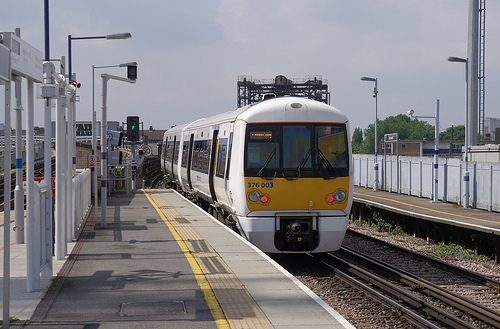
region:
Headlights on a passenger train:
[245, 188, 347, 203]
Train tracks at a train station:
[347, 225, 499, 326]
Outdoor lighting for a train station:
[66, 33, 135, 80]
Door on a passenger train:
[207, 128, 217, 202]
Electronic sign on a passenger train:
[245, 125, 277, 142]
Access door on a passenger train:
[208, 125, 220, 203]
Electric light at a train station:
[125, 115, 139, 142]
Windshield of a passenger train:
[246, 121, 350, 178]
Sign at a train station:
[2, 31, 44, 83]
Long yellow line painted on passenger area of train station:
[142, 187, 228, 327]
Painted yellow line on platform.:
[135, 183, 219, 326]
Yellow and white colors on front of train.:
[239, 98, 346, 259]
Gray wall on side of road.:
[357, 148, 494, 217]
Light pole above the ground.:
[61, 24, 133, 78]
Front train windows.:
[240, 116, 348, 179]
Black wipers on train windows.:
[240, 133, 350, 188]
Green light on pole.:
[122, 113, 144, 149]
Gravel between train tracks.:
[298, 260, 496, 302]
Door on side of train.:
[200, 125, 225, 203]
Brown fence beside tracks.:
[370, 195, 498, 255]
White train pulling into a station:
[153, 92, 359, 260]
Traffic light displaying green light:
[121, 109, 147, 190]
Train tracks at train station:
[293, 221, 499, 326]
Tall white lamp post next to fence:
[357, 70, 389, 191]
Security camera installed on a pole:
[402, 95, 445, 204]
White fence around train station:
[344, 143, 499, 217]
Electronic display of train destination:
[246, 126, 281, 143]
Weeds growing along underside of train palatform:
[348, 198, 498, 273]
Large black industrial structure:
[231, 68, 337, 111]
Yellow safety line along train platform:
[132, 182, 290, 327]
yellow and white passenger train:
[249, 112, 346, 204]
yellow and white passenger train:
[204, 117, 262, 206]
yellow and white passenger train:
[217, 104, 354, 255]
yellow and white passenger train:
[180, 127, 230, 193]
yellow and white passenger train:
[169, 137, 200, 179]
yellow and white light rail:
[248, 111, 348, 242]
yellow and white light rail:
[211, 119, 255, 200]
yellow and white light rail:
[184, 123, 234, 190]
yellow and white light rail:
[185, 133, 337, 215]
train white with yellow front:
[152, 97, 368, 265]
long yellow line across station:
[135, 185, 233, 327]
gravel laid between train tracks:
[292, 269, 498, 323]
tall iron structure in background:
[226, 68, 345, 111]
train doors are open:
[150, 112, 355, 239]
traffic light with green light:
[125, 106, 146, 188]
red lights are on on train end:
[246, 83, 360, 259]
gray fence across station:
[346, 145, 498, 211]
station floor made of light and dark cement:
[100, 197, 248, 327]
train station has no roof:
[7, 28, 497, 303]